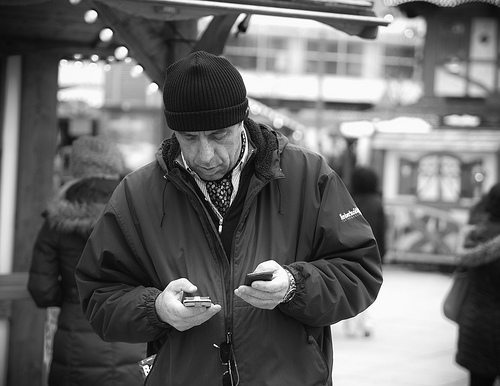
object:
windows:
[416, 149, 466, 202]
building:
[2, 0, 499, 271]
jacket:
[23, 173, 157, 385]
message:
[5, 35, 474, 365]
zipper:
[224, 329, 232, 345]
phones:
[164, 257, 291, 314]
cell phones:
[244, 270, 274, 287]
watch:
[281, 267, 298, 305]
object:
[178, 293, 213, 310]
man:
[75, 50, 383, 379]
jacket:
[455, 219, 499, 376]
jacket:
[353, 190, 388, 259]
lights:
[79, 4, 101, 27]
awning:
[0, 0, 380, 81]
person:
[441, 177, 498, 384]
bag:
[441, 263, 472, 322]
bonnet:
[56, 136, 126, 181]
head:
[58, 135, 129, 183]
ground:
[343, 322, 407, 373]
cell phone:
[183, 295, 212, 308]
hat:
[161, 52, 251, 135]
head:
[162, 47, 250, 181]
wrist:
[281, 264, 301, 308]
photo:
[2, 0, 497, 383]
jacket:
[77, 118, 383, 383]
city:
[0, 0, 499, 385]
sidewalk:
[51, 266, 460, 383]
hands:
[154, 274, 222, 332]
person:
[28, 139, 145, 386]